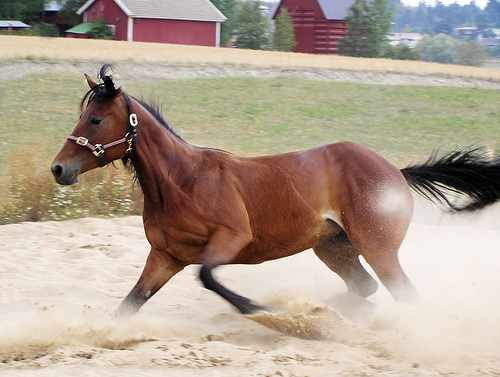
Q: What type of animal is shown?
A: Horse.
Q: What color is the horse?
A: Brown.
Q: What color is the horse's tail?
A: Black.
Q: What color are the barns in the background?
A: Red.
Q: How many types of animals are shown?
A: One.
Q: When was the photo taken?
A: Day time.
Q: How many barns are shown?
A: Two.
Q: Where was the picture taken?
A: In a field.